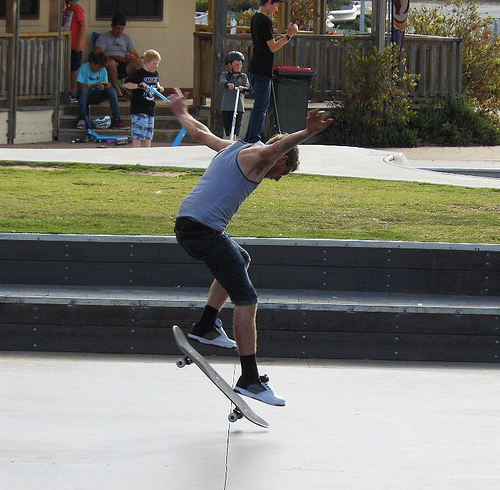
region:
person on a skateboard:
[145, 81, 347, 429]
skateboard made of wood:
[166, 322, 267, 439]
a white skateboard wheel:
[172, 353, 187, 371]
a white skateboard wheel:
[221, 409, 241, 425]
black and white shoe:
[219, 367, 290, 409]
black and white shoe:
[183, 309, 250, 355]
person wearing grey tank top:
[135, 75, 363, 433]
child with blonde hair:
[117, 47, 179, 150]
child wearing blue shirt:
[64, 48, 130, 133]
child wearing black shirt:
[237, 0, 296, 147]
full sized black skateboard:
[159, 317, 271, 432]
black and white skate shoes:
[231, 365, 288, 413]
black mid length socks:
[238, 353, 259, 383]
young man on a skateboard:
[159, 93, 335, 431]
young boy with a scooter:
[213, 48, 250, 143]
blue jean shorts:
[169, 216, 259, 308]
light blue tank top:
[168, 140, 289, 227]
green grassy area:
[2, 150, 498, 250]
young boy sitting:
[72, 46, 129, 131]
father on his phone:
[91, 11, 157, 101]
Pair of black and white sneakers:
[236, 373, 289, 406]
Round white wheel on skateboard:
[224, 412, 238, 421]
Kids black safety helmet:
[223, 50, 244, 63]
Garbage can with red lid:
[273, 65, 306, 131]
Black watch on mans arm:
[283, 33, 295, 40]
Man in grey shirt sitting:
[93, 21, 139, 56]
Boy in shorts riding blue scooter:
[136, 48, 164, 148]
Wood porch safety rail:
[421, 36, 459, 101]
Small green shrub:
[346, 43, 416, 151]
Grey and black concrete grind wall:
[314, 293, 476, 370]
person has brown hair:
[254, 123, 299, 166]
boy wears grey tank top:
[177, 152, 273, 244]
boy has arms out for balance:
[165, 93, 315, 172]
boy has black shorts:
[160, 204, 257, 306]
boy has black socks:
[202, 308, 251, 384]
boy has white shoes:
[224, 368, 291, 412]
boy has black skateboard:
[160, 328, 279, 435]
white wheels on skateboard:
[220, 411, 242, 431]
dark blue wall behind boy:
[68, 214, 170, 360]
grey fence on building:
[212, 27, 485, 102]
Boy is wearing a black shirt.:
[121, 46, 166, 148]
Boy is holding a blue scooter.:
[122, 50, 187, 146]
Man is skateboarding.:
[164, 90, 336, 432]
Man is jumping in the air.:
[162, 85, 315, 430]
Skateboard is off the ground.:
[167, 323, 273, 432]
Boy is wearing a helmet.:
[217, 46, 252, 139]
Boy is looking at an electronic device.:
[74, 47, 129, 130]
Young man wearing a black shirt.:
[243, 0, 280, 145]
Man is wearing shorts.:
[161, 83, 336, 433]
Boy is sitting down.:
[65, 47, 129, 130]